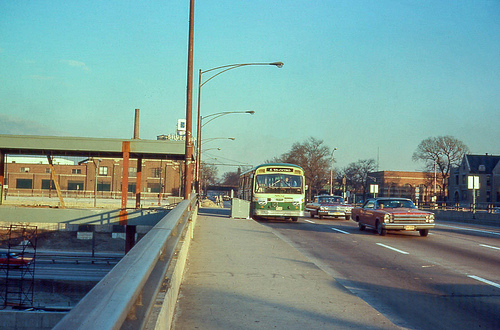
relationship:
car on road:
[0, 251, 35, 270] [0, 251, 104, 281]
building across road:
[0, 132, 201, 202] [193, 216, 493, 326]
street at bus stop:
[165, 209, 495, 329] [224, 169, 255, 223]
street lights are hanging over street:
[180, 55, 286, 210] [159, 200, 498, 326]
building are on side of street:
[0, 132, 201, 202] [159, 200, 498, 326]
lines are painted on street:
[324, 219, 498, 292] [165, 209, 495, 329]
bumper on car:
[385, 211, 436, 226] [348, 196, 436, 238]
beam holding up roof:
[120, 137, 130, 226] [0, 133, 190, 159]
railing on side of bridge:
[48, 192, 198, 329] [52, 192, 499, 329]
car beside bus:
[305, 195, 352, 222] [239, 162, 309, 224]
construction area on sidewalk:
[198, 194, 228, 210] [154, 199, 405, 329]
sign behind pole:
[175, 117, 187, 132] [183, 1, 195, 199]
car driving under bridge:
[1, 246, 33, 271] [52, 192, 499, 329]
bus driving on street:
[239, 162, 309, 224] [252, 209, 499, 329]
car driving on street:
[348, 196, 436, 238] [252, 209, 499, 329]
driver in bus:
[285, 176, 297, 188] [238, 163, 308, 220]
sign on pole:
[466, 173, 483, 192] [470, 178, 477, 208]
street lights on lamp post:
[267, 60, 287, 69] [195, 59, 285, 196]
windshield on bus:
[255, 169, 305, 193] [233, 158, 310, 228]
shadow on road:
[333, 266, 483, 328] [198, 198, 478, 327]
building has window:
[1, 131, 201, 200] [66, 174, 84, 194]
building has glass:
[0, 132, 201, 202] [13, 174, 36, 190]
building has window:
[0, 132, 201, 202] [148, 184, 166, 194]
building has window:
[1, 131, 201, 200] [95, 160, 109, 174]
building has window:
[1, 131, 201, 200] [95, 164, 109, 178]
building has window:
[0, 132, 201, 202] [122, 184, 134, 193]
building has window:
[1, 131, 201, 200] [68, 162, 86, 176]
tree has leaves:
[292, 131, 339, 196] [306, 151, 318, 169]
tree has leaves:
[409, 134, 473, 205] [422, 140, 434, 158]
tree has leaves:
[409, 134, 473, 205] [424, 140, 438, 156]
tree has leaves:
[409, 134, 473, 205] [350, 174, 360, 195]